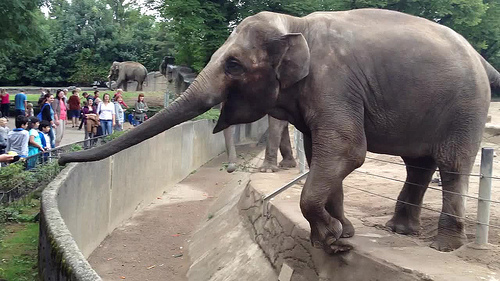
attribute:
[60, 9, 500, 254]
elephant — here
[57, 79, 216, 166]
trunk — here, black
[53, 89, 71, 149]
lady — light, here, standing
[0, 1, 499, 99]
tree — green, here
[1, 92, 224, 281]
grass — green, here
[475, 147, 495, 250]
pole — here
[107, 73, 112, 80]
tusk — here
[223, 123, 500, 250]
fence — wired, present, here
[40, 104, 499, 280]
pen — gray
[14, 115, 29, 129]
hair — black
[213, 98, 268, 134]
mouth — open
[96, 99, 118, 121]
shirt — white